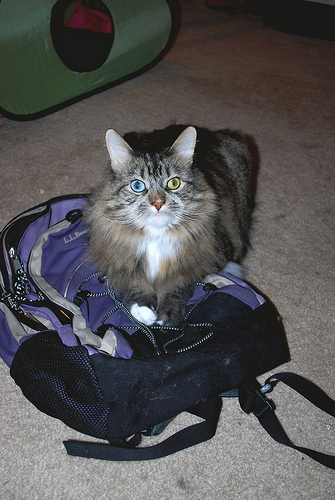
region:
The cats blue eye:
[128, 177, 144, 190]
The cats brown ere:
[161, 176, 183, 191]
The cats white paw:
[128, 296, 152, 322]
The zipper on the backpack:
[6, 248, 24, 276]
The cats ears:
[102, 127, 195, 171]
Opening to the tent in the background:
[36, 0, 122, 74]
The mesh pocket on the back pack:
[4, 332, 133, 443]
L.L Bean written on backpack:
[53, 226, 91, 244]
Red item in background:
[62, 9, 109, 34]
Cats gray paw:
[156, 296, 185, 323]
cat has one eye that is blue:
[123, 172, 152, 203]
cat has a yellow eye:
[156, 171, 187, 198]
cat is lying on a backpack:
[95, 110, 286, 324]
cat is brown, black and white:
[96, 115, 250, 350]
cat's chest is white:
[140, 216, 175, 269]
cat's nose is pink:
[146, 199, 165, 213]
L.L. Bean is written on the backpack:
[58, 225, 97, 244]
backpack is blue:
[26, 176, 289, 399]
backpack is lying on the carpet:
[143, 278, 330, 448]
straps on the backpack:
[70, 375, 326, 492]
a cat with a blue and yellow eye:
[85, 160, 220, 218]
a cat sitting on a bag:
[67, 81, 292, 399]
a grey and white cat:
[73, 95, 290, 284]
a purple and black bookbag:
[39, 139, 329, 482]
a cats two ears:
[99, 115, 217, 160]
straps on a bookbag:
[87, 324, 306, 475]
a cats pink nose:
[135, 191, 169, 214]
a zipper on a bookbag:
[0, 237, 32, 280]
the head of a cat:
[106, 116, 245, 235]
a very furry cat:
[79, 92, 295, 291]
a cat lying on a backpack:
[13, 105, 294, 394]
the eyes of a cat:
[125, 174, 187, 195]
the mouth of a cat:
[142, 208, 173, 219]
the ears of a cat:
[103, 126, 200, 164]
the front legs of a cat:
[114, 267, 191, 324]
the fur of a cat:
[202, 151, 241, 242]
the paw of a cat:
[129, 299, 161, 331]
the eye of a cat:
[127, 174, 147, 196]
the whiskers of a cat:
[83, 193, 147, 233]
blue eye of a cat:
[130, 178, 146, 192]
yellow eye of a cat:
[166, 176, 182, 189]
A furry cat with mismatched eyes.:
[82, 119, 254, 328]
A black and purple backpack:
[0, 192, 334, 470]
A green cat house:
[0, 0, 183, 122]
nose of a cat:
[150, 199, 164, 208]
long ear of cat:
[103, 127, 136, 174]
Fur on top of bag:
[95, 292, 286, 430]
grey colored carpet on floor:
[0, 0, 334, 499]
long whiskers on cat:
[84, 194, 153, 225]